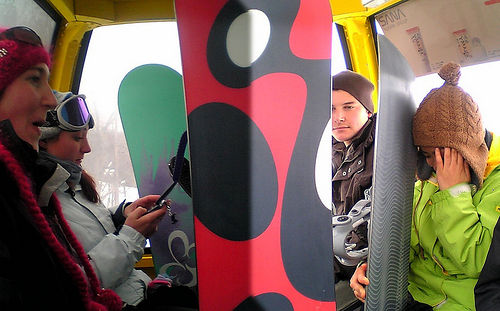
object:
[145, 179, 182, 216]
cellular phone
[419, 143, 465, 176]
face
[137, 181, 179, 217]
cell phone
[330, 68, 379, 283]
man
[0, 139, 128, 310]
sweater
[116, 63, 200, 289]
snowboard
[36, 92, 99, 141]
goggles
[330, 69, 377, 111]
beanie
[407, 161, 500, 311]
green jacket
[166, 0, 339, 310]
snowboard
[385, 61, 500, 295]
person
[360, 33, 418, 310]
board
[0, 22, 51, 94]
cap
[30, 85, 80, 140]
knitted cap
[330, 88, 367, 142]
face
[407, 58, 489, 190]
ski cap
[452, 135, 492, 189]
flaps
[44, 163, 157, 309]
jacket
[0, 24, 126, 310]
female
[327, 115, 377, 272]
jacket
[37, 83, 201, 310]
girl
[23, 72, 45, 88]
eye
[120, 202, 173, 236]
hands